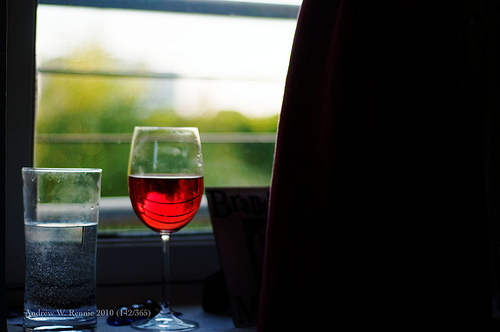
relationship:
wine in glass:
[127, 174, 204, 230] [128, 126, 206, 331]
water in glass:
[24, 221, 99, 321] [20, 165, 103, 332]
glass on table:
[128, 126, 206, 331] [6, 305, 238, 331]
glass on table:
[20, 165, 103, 332] [6, 305, 238, 331]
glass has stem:
[128, 126, 206, 331] [160, 232, 171, 310]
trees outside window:
[35, 42, 281, 187] [32, 3, 304, 241]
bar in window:
[34, 194, 137, 225] [32, 3, 304, 241]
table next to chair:
[6, 305, 238, 331] [255, 1, 500, 332]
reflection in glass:
[136, 179, 203, 231] [128, 126, 206, 331]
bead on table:
[114, 306, 132, 327] [6, 305, 238, 331]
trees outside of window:
[35, 42, 281, 187] [32, 3, 304, 241]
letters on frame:
[211, 187, 269, 218] [204, 186, 271, 331]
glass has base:
[128, 126, 206, 331] [133, 309, 200, 332]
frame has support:
[204, 186, 271, 331] [200, 269, 231, 318]